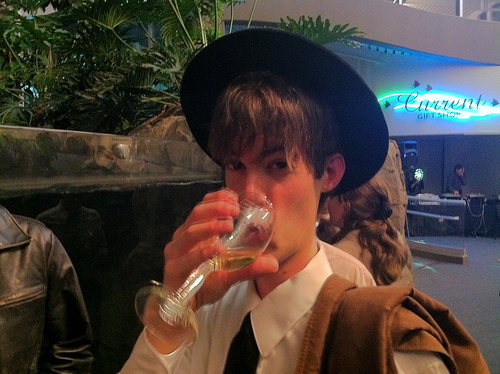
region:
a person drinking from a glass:
[132, 91, 356, 370]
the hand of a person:
[159, 176, 231, 273]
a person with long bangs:
[204, 63, 341, 178]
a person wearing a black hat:
[182, 6, 394, 190]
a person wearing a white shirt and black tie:
[127, 225, 349, 371]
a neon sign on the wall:
[388, 75, 498, 138]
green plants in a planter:
[36, 14, 159, 143]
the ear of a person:
[320, 148, 345, 193]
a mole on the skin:
[279, 258, 293, 277]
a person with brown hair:
[198, 61, 341, 166]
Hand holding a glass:
[141, 185, 297, 329]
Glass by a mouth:
[144, 187, 298, 360]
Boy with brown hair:
[195, 67, 396, 295]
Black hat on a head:
[173, 22, 402, 216]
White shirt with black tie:
[153, 238, 386, 368]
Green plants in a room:
[3, 11, 210, 135]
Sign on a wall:
[367, 78, 492, 160]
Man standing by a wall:
[441, 161, 480, 225]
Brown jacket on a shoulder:
[285, 265, 464, 369]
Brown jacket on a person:
[0, 207, 92, 372]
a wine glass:
[133, 187, 276, 350]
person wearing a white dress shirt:
[110, 243, 450, 372]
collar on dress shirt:
[218, 242, 331, 357]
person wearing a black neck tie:
[219, 310, 269, 372]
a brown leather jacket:
[0, 205, 97, 370]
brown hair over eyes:
[207, 72, 337, 174]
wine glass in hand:
[132, 185, 280, 351]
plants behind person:
[1, 0, 225, 132]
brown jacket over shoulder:
[295, 270, 492, 372]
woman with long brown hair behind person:
[326, 175, 417, 286]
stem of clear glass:
[124, 282, 211, 348]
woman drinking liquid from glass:
[193, 172, 329, 292]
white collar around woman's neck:
[213, 291, 326, 356]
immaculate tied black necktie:
[208, 305, 299, 372]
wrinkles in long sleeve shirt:
[10, 238, 88, 290]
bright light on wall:
[377, 62, 498, 145]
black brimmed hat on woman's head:
[183, 10, 459, 159]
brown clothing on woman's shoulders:
[300, 249, 471, 358]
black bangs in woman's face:
[161, 66, 335, 173]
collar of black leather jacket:
[6, 207, 91, 273]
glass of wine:
[145, 175, 280, 340]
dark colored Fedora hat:
[175, 22, 391, 207]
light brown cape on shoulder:
[305, 275, 495, 370]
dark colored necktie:
[210, 297, 267, 367]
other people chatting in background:
[315, 166, 420, 281]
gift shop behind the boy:
[375, 70, 495, 140]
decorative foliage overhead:
[5, 0, 223, 120]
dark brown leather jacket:
[1, 208, 111, 363]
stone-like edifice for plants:
[5, 127, 235, 193]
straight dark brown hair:
[206, 68, 346, 151]